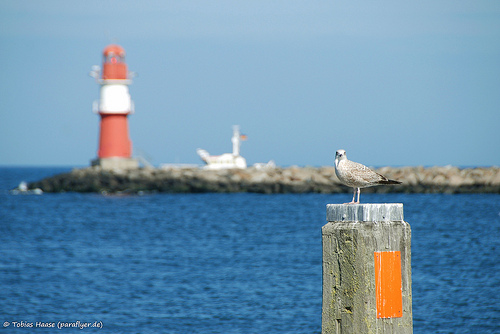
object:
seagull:
[334, 149, 402, 205]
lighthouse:
[87, 44, 136, 164]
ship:
[196, 126, 249, 169]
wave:
[132, 199, 206, 233]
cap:
[326, 203, 404, 222]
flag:
[241, 134, 247, 140]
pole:
[319, 218, 418, 334]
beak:
[339, 154, 344, 157]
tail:
[378, 175, 404, 185]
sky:
[0, 0, 500, 169]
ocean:
[0, 163, 500, 334]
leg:
[344, 187, 361, 204]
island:
[3, 161, 499, 197]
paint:
[375, 251, 401, 318]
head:
[335, 149, 346, 160]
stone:
[7, 166, 99, 195]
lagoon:
[0, 164, 500, 334]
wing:
[355, 161, 389, 187]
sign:
[373, 250, 405, 319]